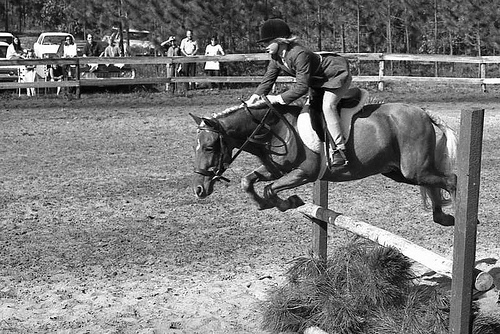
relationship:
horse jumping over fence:
[191, 100, 461, 228] [301, 101, 485, 333]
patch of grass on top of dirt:
[268, 237, 450, 332] [4, 103, 496, 332]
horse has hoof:
[191, 100, 461, 228] [288, 195, 305, 209]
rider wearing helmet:
[249, 20, 353, 167] [255, 20, 292, 41]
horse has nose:
[191, 100, 461, 228] [191, 176, 210, 201]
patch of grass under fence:
[268, 237, 450, 332] [301, 101, 485, 333]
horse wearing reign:
[191, 100, 461, 228] [194, 99, 278, 183]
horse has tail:
[191, 100, 461, 228] [421, 109, 459, 209]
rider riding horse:
[249, 20, 353, 167] [191, 100, 461, 228]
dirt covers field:
[4, 103, 496, 332] [2, 87, 491, 327]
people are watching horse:
[7, 29, 223, 74] [191, 100, 461, 228]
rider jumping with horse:
[249, 20, 353, 167] [191, 100, 461, 228]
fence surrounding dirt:
[4, 51, 499, 95] [4, 103, 496, 332]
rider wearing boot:
[249, 20, 353, 167] [331, 149, 348, 169]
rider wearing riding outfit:
[249, 20, 353, 167] [268, 53, 355, 147]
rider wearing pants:
[249, 20, 353, 167] [323, 88, 351, 153]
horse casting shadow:
[191, 100, 461, 228] [402, 254, 496, 314]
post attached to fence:
[449, 106, 488, 332] [301, 101, 485, 333]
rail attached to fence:
[298, 196, 497, 289] [301, 101, 485, 333]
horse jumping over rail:
[191, 100, 461, 228] [298, 196, 497, 289]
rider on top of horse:
[249, 20, 353, 167] [191, 100, 461, 228]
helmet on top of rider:
[255, 20, 292, 41] [249, 20, 353, 167]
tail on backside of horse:
[421, 109, 459, 209] [191, 100, 461, 228]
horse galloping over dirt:
[191, 100, 461, 228] [4, 103, 496, 332]